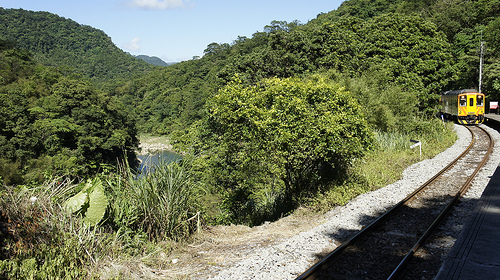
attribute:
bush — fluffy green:
[182, 72, 369, 226]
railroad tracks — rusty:
[289, 122, 495, 279]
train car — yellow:
[439, 84, 490, 130]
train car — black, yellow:
[435, 82, 466, 117]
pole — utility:
[476, 44, 483, 91]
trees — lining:
[115, 25, 420, 227]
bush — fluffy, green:
[116, 162, 216, 230]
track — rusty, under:
[295, 120, 499, 277]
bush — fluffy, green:
[3, 82, 128, 204]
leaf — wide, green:
[208, 86, 318, 173]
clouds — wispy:
[123, 0, 195, 65]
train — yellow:
[434, 85, 486, 128]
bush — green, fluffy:
[3, 68, 140, 185]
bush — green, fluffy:
[400, 2, 497, 88]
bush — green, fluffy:
[219, 84, 381, 212]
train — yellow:
[405, 80, 496, 133]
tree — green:
[4, 48, 146, 181]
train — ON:
[439, 87, 487, 127]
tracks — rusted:
[356, 141, 456, 268]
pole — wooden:
[478, 39, 484, 96]